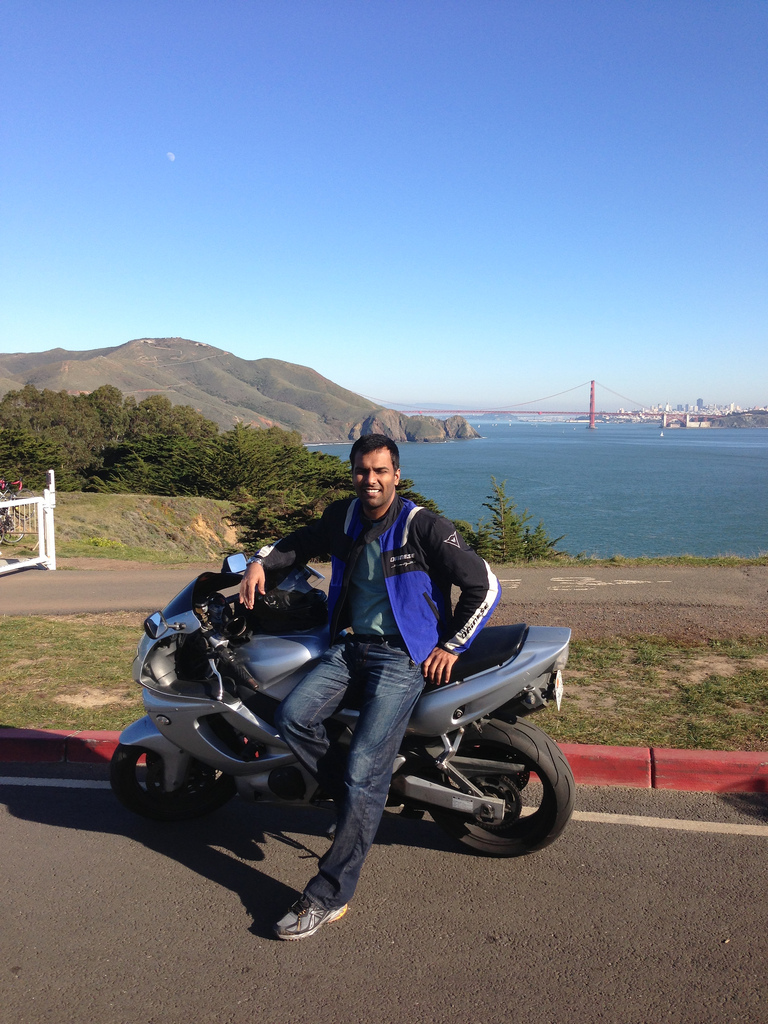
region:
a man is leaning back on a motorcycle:
[104, 430, 579, 936]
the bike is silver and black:
[105, 546, 587, 946]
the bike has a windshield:
[125, 557, 247, 730]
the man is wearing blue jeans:
[282, 634, 432, 928]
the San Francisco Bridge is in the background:
[384, 371, 758, 453]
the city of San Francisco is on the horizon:
[605, 393, 767, 436]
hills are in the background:
[11, 331, 479, 459]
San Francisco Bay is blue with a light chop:
[314, 407, 766, 558]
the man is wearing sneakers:
[273, 889, 355, 948]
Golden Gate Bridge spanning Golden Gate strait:
[386, 377, 730, 423]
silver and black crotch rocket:
[100, 543, 578, 854]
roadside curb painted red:
[6, 722, 763, 799]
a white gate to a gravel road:
[0, 469, 63, 576]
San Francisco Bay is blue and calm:
[325, 413, 766, 575]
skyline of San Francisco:
[600, 390, 751, 416]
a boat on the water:
[651, 423, 675, 443]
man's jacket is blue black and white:
[266, 486, 489, 659]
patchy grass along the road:
[11, 610, 766, 749]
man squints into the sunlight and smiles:
[349, 431, 406, 522]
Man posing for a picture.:
[232, 416, 517, 947]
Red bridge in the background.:
[383, 359, 762, 452]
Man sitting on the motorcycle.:
[101, 407, 598, 942]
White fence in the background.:
[1, 458, 72, 595]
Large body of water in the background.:
[301, 387, 767, 571]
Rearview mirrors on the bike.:
[140, 543, 250, 640]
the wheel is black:
[411, 706, 590, 892]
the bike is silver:
[76, 523, 556, 774]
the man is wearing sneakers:
[194, 823, 389, 959]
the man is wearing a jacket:
[201, 384, 543, 724]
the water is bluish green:
[447, 408, 733, 559]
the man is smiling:
[323, 407, 412, 513]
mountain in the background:
[34, 319, 412, 459]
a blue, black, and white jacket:
[250, 498, 501, 658]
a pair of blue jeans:
[280, 636, 430, 905]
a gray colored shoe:
[271, 897, 349, 941]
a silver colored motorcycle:
[109, 554, 573, 942]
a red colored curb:
[2, 727, 766, 796]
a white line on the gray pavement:
[0, 770, 764, 839]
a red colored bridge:
[395, 376, 763, 428]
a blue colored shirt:
[343, 510, 400, 637]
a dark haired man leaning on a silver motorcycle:
[108, 428, 574, 940]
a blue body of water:
[304, 422, 766, 558]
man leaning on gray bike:
[98, 429, 591, 841]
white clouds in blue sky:
[285, 139, 295, 154]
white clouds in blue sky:
[190, 245, 273, 302]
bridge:
[458, 359, 664, 442]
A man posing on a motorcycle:
[96, 423, 590, 951]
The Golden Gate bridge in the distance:
[416, 377, 711, 428]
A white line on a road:
[571, 793, 758, 841]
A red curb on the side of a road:
[537, 740, 761, 795]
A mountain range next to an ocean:
[10, 333, 488, 456]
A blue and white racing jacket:
[263, 490, 499, 684]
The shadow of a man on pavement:
[0, 720, 338, 939]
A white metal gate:
[0, 468, 63, 579]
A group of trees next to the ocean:
[7, 375, 354, 515]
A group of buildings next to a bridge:
[662, 395, 758, 419]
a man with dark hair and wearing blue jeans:
[237, 433, 501, 943]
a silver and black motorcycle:
[109, 540, 575, 859]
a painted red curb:
[3, 726, 765, 790]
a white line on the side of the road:
[0, 775, 765, 839]